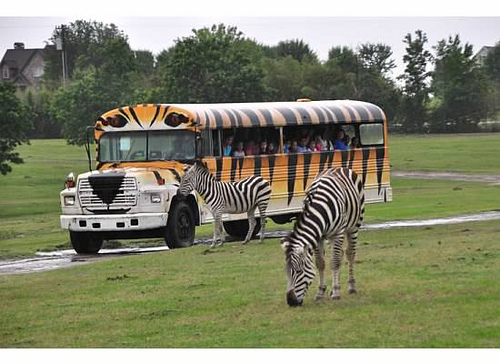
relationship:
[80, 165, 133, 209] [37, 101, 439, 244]
nose painted on bus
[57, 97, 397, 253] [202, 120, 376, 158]
bus of windows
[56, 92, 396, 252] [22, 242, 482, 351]
bus in a field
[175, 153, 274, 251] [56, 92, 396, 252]
zebra by a bus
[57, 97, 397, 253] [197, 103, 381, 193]
bus with black stripes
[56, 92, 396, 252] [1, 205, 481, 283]
bus driving in on path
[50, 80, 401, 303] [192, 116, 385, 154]
kids looking out bus window